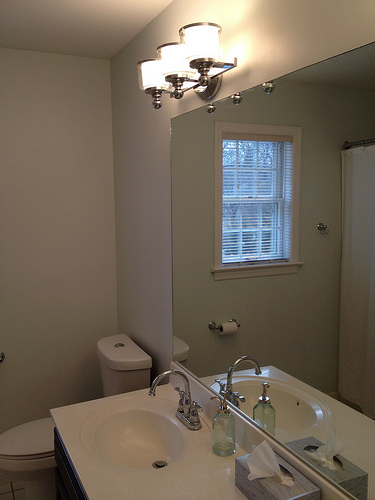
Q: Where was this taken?
A: A bathroom.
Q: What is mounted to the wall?
A: A large mirror.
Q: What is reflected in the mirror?
A: A window.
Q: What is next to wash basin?
A: A toilet.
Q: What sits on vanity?
A: Hand soap and tissue box.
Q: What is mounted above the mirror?
A: Light fixtures.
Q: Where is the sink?
A: In the bathroom.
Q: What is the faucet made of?
A: Shiny metal.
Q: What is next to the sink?
A: A bottle of hand soap.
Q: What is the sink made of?
A: White porcelain.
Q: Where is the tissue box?
A: Next to the hand soap.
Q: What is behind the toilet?
A: The wall.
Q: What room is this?
A: Bathroom.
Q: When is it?
A: Day time.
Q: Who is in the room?
A: No one.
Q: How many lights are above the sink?
A: 3.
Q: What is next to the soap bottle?
A: Tissues.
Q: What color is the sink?
A: White.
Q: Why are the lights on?
A: So people can see.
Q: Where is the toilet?
A: Next to the sink.